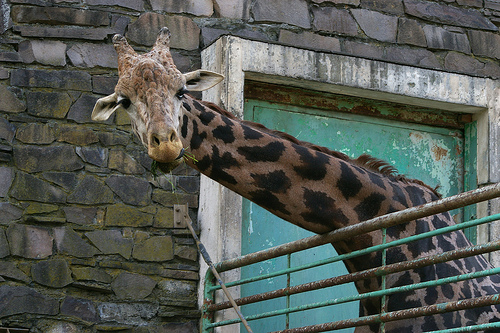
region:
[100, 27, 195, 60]
the horns are spotted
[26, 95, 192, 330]
the wall is stone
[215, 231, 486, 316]
the gate is rusted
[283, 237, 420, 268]
the bar is green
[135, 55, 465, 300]
giraffe is behind gate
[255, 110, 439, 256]
the door is faded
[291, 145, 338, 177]
black stripes on giraffe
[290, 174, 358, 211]
brown color on the giraffe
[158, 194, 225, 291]
silver pole on the wall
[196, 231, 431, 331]
iron grate attached to the wall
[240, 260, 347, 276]
green paint on the railing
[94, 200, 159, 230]
green tiles on the wall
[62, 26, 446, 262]
giraffe looking over the railing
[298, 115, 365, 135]
blue paint on door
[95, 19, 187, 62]
horns on giraffe's head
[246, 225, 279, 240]
chipped paint on door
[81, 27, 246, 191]
head of the giraffe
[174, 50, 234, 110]
ear of the giraffe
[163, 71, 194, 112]
eye of the giraffe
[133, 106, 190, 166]
nose of the giraffe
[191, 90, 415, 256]
neck of the giraffe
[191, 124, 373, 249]
dark spots on giraffe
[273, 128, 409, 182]
hair on back of giraffe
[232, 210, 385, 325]
bars in front of giraffe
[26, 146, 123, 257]
wall next to giraffe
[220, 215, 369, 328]
different colored bars in front of giraffe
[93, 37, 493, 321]
giraffe looking over a gate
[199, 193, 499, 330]
white and green gate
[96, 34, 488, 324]
giraffe eating plants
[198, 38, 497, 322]
doorway with white frame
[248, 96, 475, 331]
closed green door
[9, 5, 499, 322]
grey stone building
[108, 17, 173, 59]
small horns on the giraffe's head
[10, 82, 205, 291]
green algae on the stone building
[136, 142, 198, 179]
plant giraffe is chewing on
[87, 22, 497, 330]
a giraffe looking forward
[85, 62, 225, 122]
ears of the animal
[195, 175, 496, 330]
a fence around giraffe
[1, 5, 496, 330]
the stone wall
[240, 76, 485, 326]
the green door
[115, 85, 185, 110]
the eyes of giraffe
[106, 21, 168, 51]
the horns on animal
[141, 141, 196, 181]
food in the mouth of giraffe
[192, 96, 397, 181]
mane of neck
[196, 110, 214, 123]
black spot on giraffe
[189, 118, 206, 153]
black spot on giraffe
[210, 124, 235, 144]
black spot on giraffe